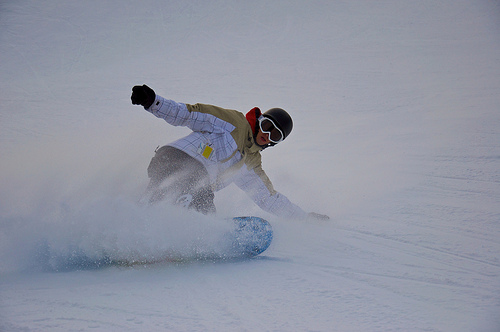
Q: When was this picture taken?
A: Daytime.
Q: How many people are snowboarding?
A: One.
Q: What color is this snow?
A: White.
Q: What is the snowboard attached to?
A: His feet.